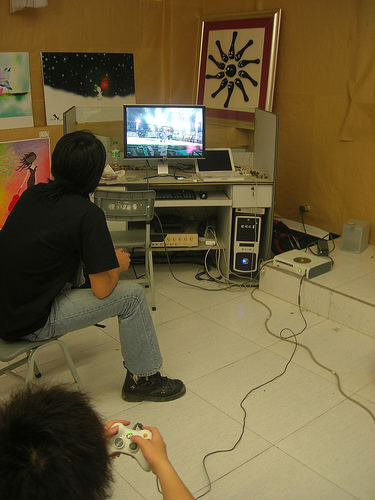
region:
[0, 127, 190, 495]
Two men playing video games.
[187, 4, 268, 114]
Black, red, and white framed art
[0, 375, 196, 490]
Man holding video game controller in his hands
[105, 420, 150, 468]
White and gray video game controller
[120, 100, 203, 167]
Flat screen tv sitting on a desk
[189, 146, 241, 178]
White laptop sitting on a table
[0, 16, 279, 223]
Four pieces of art in the room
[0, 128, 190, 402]
Man wearing a short sleeved black shirt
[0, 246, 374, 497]
White tiled floor in the room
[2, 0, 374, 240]
Brown paper covering the walls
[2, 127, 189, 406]
A MAN PLAYING A VIDEO GAME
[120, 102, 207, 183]
A FLAT SCREEN MONITOR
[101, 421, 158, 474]
A WHITE GAME CONTROLLER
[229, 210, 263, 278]
A HARD DRIVE COMPUTER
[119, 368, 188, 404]
A BLACK SNEAKER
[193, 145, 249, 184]
A WHITE LAPTOP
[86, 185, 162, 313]
A GRAY PLASTIC CHAIR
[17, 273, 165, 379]
A PAIR OF BLUE JEANS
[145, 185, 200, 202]
A BLACK KEYBOARD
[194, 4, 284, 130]
A PICTURE HANGING ON A WALL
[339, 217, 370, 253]
gray speaker on the step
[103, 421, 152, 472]
white xbox controller in the hands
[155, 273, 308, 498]
gray xbox controller cord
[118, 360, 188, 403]
black shoe on the man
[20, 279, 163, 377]
blue jeans on the man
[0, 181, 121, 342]
black shirt on the man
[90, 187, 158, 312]
gray chair at the desk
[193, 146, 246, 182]
white laptop on the desk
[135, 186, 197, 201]
black computer keyboard on the desk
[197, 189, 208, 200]
black computer mouse on the desk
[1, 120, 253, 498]
two guys playing video games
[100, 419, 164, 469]
white and gray xbox controller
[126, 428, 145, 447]
thumb on the controller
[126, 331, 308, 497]
gray cord from the controller laying along the ground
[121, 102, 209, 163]
monitor is on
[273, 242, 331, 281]
white and gray xbox console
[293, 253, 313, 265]
disk sitting on top of the console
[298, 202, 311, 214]
outlet on the wall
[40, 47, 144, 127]
artwork leaning on the wall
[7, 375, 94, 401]
tufts of hair sticking off the head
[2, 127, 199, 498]
Two people playing video games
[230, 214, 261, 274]
Desktop computer modem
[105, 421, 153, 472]
White video game controller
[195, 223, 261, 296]
mess of multiple cords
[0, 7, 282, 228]
Four pieces of artwork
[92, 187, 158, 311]
Grey fold-up chair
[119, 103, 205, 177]
Flatscreen desktop computer monitor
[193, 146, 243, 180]
White laptop computer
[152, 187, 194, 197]
Black computer keyboard on pullout drawer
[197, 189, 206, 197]
Black computer mouse on pullout drawer